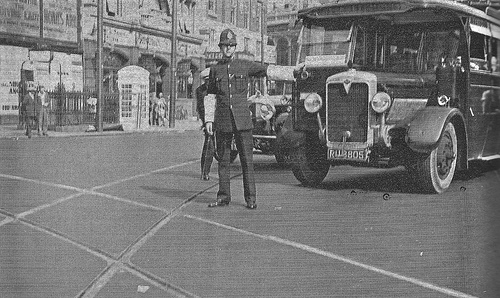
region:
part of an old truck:
[277, 0, 497, 198]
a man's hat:
[219, 29, 238, 47]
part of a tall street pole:
[90, 1, 106, 131]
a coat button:
[226, 82, 232, 90]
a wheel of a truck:
[412, 120, 461, 197]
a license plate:
[326, 146, 368, 161]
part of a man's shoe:
[245, 200, 258, 210]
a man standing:
[189, 21, 309, 216]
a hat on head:
[212, 27, 242, 52]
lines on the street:
[1, 147, 498, 297]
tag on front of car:
[322, 147, 375, 162]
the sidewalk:
[0, 112, 210, 137]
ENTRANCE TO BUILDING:
[110, 64, 155, 130]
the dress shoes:
[206, 194, 260, 212]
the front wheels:
[214, 122, 464, 197]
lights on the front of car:
[255, 87, 450, 122]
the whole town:
[0, 5, 493, 296]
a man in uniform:
[190, 26, 267, 223]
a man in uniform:
[174, 14, 301, 230]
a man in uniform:
[176, 34, 271, 221]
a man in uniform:
[185, 8, 305, 230]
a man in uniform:
[191, 20, 280, 231]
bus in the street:
[228, 17, 470, 234]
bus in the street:
[277, 8, 465, 225]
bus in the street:
[273, 6, 465, 213]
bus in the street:
[266, 5, 478, 219]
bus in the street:
[259, 15, 470, 210]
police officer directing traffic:
[185, 29, 292, 214]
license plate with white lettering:
[327, 141, 364, 164]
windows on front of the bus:
[293, 22, 439, 77]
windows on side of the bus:
[465, 34, 494, 72]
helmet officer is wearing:
[217, 32, 236, 44]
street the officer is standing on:
[5, 134, 477, 297]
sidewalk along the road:
[30, 109, 210, 137]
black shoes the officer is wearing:
[201, 194, 256, 214]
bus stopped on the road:
[288, 12, 490, 187]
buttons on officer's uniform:
[223, 64, 235, 109]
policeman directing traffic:
[193, 24, 315, 209]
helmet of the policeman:
[214, 29, 235, 48]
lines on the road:
[5, 155, 477, 297]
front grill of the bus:
[328, 87, 368, 143]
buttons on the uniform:
[227, 63, 236, 110]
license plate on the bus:
[325, 147, 365, 160]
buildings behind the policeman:
[5, 1, 321, 141]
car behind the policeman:
[232, 62, 303, 156]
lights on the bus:
[299, 89, 396, 116]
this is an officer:
[185, 18, 312, 220]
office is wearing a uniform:
[165, 17, 331, 217]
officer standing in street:
[175, 22, 335, 228]